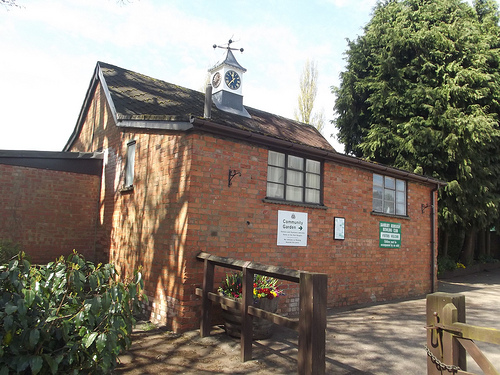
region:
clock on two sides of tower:
[209, 68, 244, 90]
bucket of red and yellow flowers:
[215, 267, 282, 337]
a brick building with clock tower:
[0, 33, 447, 332]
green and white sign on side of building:
[376, 218, 403, 251]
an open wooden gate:
[190, 247, 498, 372]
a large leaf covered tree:
[326, 0, 498, 267]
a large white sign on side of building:
[273, 208, 310, 248]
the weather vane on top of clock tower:
[212, 33, 245, 54]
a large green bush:
[0, 248, 150, 373]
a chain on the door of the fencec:
[421, 340, 462, 372]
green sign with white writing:
[378, 219, 400, 250]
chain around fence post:
[420, 342, 461, 373]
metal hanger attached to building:
[227, 165, 242, 188]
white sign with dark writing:
[277, 208, 309, 249]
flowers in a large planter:
[220, 266, 282, 343]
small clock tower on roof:
[208, 35, 249, 117]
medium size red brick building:
[0, 63, 440, 332]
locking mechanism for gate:
[424, 306, 444, 359]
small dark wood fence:
[196, 249, 331, 374]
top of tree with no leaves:
[292, 54, 319, 123]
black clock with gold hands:
[223, 70, 240, 90]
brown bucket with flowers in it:
[219, 272, 278, 334]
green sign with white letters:
[378, 220, 399, 245]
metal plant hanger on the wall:
[226, 168, 241, 184]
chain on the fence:
[425, 346, 457, 368]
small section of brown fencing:
[195, 251, 326, 371]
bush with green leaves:
[5, 249, 150, 371]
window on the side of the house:
[121, 141, 135, 188]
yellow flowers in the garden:
[453, 261, 463, 269]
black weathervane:
[211, 38, 242, 54]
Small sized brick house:
[138, 104, 450, 302]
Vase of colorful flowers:
[258, 283, 278, 303]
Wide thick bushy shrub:
[14, 263, 136, 365]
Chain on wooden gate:
[426, 343, 458, 374]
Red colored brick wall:
[202, 183, 242, 248]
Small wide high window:
[265, 153, 331, 208]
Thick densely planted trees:
[448, 108, 495, 250]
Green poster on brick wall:
[371, 218, 406, 253]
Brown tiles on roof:
[123, 74, 175, 109]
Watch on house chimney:
[208, 65, 253, 93]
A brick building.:
[14, 38, 463, 313]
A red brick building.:
[6, 55, 443, 317]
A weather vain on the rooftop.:
[204, 28, 254, 112]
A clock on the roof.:
[206, 40, 256, 117]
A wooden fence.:
[194, 246, 498, 373]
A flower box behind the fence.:
[216, 267, 295, 314]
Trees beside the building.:
[338, 27, 493, 281]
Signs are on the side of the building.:
[266, 207, 411, 259]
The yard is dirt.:
[131, 249, 494, 369]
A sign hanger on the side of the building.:
[220, 163, 246, 192]